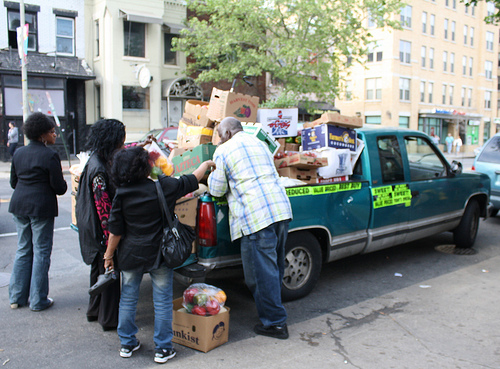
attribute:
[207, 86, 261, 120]
box — cardboard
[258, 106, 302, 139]
box — cardboard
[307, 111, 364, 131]
box — cardboard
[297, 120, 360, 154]
box — cardboard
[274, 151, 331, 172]
box — cardboard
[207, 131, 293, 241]
shirt — plaid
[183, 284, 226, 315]
bag — plastic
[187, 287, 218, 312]
produce — colorful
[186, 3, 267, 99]
building — narrow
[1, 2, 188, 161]
building — narrow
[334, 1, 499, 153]
building — large, tan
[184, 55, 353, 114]
tree — large and airy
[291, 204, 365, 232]
truck — blue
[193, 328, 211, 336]
box — brown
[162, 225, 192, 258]
purse — black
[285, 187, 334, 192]
stickers — neon green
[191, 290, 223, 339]
vegetables —  colorful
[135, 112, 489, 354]
truck — blue-green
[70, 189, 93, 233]
jacket — black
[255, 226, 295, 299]
jeans — blue